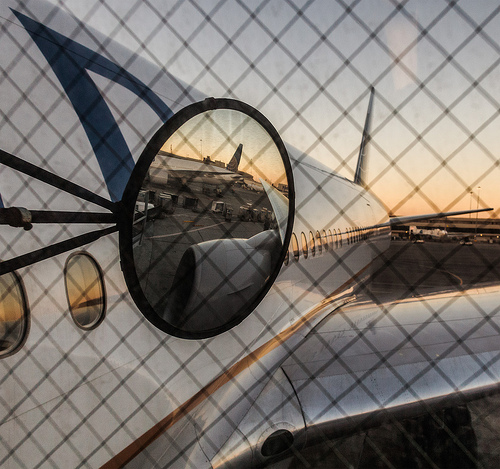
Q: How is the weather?
A: It is sunny.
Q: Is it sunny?
A: Yes, it is sunny.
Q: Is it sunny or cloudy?
A: It is sunny.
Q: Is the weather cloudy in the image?
A: No, it is sunny.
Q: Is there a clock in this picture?
A: No, there are no clocks.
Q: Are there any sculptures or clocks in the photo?
A: No, there are no clocks or sculptures.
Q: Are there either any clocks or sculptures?
A: No, there are no clocks or sculptures.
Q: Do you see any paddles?
A: No, there are no paddles.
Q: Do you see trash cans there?
A: No, there are no trash cans.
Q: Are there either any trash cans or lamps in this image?
A: No, there are no trash cans or lamps.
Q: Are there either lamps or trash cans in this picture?
A: No, there are no trash cans or lamps.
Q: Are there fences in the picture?
A: Yes, there is a fence.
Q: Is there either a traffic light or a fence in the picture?
A: Yes, there is a fence.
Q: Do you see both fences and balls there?
A: No, there is a fence but no balls.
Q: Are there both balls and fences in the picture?
A: No, there is a fence but no balls.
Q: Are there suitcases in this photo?
A: No, there are no suitcases.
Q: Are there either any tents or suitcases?
A: No, there are no suitcases or tents.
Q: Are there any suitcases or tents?
A: No, there are no suitcases or tents.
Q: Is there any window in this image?
A: Yes, there is a window.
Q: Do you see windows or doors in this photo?
A: Yes, there is a window.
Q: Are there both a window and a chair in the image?
A: No, there is a window but no chairs.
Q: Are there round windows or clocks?
A: Yes, there is a round window.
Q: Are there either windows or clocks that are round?
A: Yes, the window is round.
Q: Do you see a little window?
A: Yes, there is a little window.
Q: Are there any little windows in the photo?
A: Yes, there is a little window.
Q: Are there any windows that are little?
A: Yes, there is a window that is little.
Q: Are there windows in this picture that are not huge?
A: Yes, there is a little window.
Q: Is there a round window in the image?
A: Yes, there is a round window.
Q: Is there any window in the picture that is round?
A: Yes, there is a window that is round.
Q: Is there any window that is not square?
A: Yes, there is a round window.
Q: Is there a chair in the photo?
A: No, there are no chairs.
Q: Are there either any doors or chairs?
A: No, there are no chairs or doors.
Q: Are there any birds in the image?
A: No, there are no birds.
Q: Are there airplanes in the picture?
A: Yes, there is an airplane.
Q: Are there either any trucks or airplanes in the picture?
A: Yes, there is an airplane.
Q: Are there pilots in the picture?
A: No, there are no pilots.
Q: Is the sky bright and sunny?
A: Yes, the sky is bright and sunny.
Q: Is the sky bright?
A: Yes, the sky is bright.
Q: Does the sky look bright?
A: Yes, the sky is bright.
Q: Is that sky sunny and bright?
A: Yes, the sky is sunny and bright.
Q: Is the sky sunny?
A: Yes, the sky is sunny.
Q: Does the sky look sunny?
A: Yes, the sky is sunny.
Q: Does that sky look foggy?
A: No, the sky is sunny.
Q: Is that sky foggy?
A: No, the sky is sunny.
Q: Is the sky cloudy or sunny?
A: The sky is sunny.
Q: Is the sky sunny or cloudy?
A: The sky is sunny.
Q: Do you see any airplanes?
A: Yes, there is an airplane.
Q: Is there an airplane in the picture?
A: Yes, there is an airplane.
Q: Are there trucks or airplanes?
A: Yes, there is an airplane.